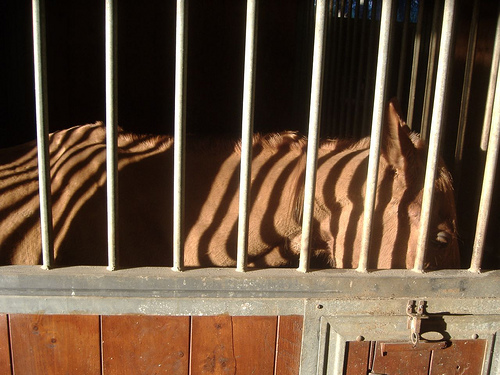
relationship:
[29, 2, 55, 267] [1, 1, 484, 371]
bar bolted into enclosure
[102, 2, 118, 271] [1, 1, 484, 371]
bar bolted into enclosure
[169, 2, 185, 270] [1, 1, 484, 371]
bar bolted into enclosure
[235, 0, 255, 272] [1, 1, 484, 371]
bar bolted into enclosure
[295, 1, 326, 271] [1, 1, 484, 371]
bar bolted into enclosure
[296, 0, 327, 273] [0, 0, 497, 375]
metal bar bolted into stall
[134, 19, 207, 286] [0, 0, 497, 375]
bar bolted into stall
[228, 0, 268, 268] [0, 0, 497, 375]
bar bolted into stall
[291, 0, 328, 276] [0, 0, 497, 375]
metal bar bolted into stall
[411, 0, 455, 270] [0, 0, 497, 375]
bar bolted into stall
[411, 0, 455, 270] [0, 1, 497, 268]
bar of a horse stall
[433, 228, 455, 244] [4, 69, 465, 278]
eye of a horse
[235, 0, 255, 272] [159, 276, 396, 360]
bar across top of stall wall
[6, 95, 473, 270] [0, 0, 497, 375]
horse in stall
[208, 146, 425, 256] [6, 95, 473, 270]
shadow on horse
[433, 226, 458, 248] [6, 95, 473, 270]
eye on horse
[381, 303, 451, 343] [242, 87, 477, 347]
latch attached to door